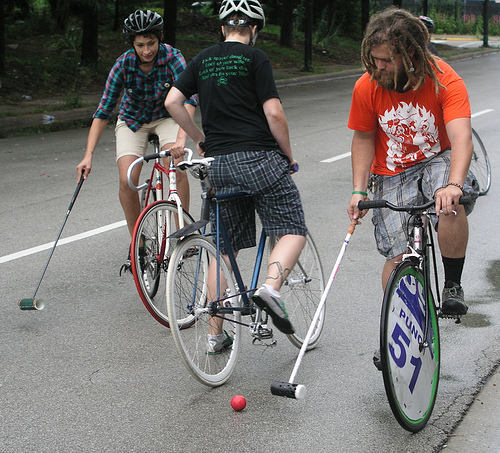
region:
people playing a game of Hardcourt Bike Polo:
[15, 0, 486, 432]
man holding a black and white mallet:
[270, 186, 367, 396]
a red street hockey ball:
[228, 392, 246, 411]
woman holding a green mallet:
[20, 155, 92, 310]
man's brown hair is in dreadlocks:
[361, 7, 447, 97]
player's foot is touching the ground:
[204, 315, 236, 360]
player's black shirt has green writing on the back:
[172, 40, 282, 156]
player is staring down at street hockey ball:
[230, 14, 425, 411]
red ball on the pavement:
[224, 380, 251, 417]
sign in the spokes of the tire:
[382, 315, 434, 400]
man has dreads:
[346, 11, 451, 93]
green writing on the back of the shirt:
[188, 50, 251, 101]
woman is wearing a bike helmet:
[108, 0, 168, 46]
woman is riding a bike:
[89, 20, 184, 208]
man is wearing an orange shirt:
[347, 65, 459, 184]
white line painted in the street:
[6, 223, 111, 263]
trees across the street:
[31, 20, 117, 64]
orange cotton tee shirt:
[343, 57, 475, 174]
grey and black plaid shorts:
[363, 149, 482, 256]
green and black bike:
[355, 193, 457, 433]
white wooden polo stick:
[271, 209, 368, 401]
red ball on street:
[231, 395, 246, 410]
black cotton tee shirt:
[173, 43, 281, 156]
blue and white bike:
[166, 193, 325, 385]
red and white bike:
[118, 131, 212, 332]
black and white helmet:
[216, 2, 267, 27]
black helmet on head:
[119, 7, 163, 37]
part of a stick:
[276, 369, 293, 395]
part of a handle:
[299, 264, 339, 339]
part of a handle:
[308, 265, 333, 332]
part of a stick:
[258, 343, 310, 433]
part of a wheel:
[203, 326, 236, 391]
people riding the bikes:
[71, 12, 482, 446]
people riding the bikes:
[71, 16, 495, 438]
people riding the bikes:
[97, 13, 473, 419]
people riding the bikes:
[71, 14, 436, 449]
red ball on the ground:
[221, 377, 258, 429]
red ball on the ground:
[212, 380, 252, 422]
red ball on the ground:
[205, 371, 269, 439]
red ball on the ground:
[211, 381, 261, 435]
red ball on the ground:
[212, 370, 269, 432]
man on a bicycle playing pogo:
[270, 10, 480, 433]